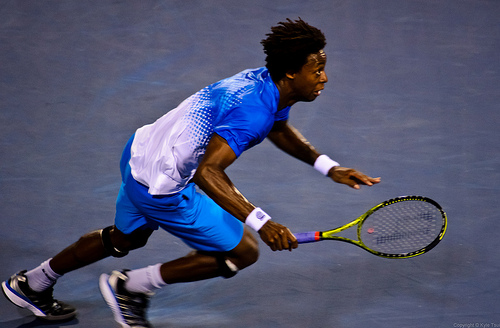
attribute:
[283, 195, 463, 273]
tennis racket — yellow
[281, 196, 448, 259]
racket — black, yellow, tennis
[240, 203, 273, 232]
wrist band — white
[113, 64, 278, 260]
blue outfit — bright, blue and white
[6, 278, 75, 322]
tennis shoes — white, black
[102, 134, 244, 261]
shorts — man's, blue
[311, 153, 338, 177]
wrist band — white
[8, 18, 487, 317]
player — slanted forward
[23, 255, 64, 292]
sock — white, black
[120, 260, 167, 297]
sock — white, black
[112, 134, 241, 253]
shorts — blue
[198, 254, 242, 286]
band — black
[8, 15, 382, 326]
man — playing tennis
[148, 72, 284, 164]
checkerboard — blue, white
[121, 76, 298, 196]
shirt — blue, white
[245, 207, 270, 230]
band — white, elastic, cotton, sport, wrist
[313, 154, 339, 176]
band — white, elastic, cotton, sport, wrist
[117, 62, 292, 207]
shirt — blue, white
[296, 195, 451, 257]
racquet — tennis racquet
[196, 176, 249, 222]
muscle — long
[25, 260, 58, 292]
sock — white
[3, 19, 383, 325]
player — tennis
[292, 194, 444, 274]
raquet — red, yellow, black, tennis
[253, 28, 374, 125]
face — showing deep concentration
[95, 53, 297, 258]
player — running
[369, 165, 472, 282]
p logo — Prince sporting goods company, stylized 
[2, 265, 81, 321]
sneakers — black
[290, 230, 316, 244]
handle — purple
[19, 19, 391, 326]
athlete — playing tennis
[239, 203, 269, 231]
wristband — white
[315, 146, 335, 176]
wristband — white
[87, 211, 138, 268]
band — black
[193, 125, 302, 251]
arm — man's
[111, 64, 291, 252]
tennis clothes — blue and white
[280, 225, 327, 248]
wrap — purple, grip